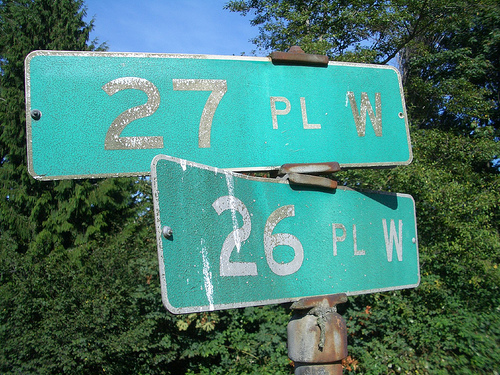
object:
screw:
[162, 226, 174, 242]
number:
[265, 204, 305, 277]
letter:
[300, 97, 324, 130]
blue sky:
[77, 2, 408, 71]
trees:
[1, 223, 162, 374]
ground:
[373, 185, 394, 211]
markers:
[15, 43, 420, 313]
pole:
[288, 293, 345, 374]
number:
[174, 77, 242, 150]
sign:
[21, 47, 414, 182]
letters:
[331, 218, 403, 263]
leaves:
[414, 15, 497, 58]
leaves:
[447, 241, 495, 284]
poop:
[173, 250, 261, 305]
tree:
[4, 1, 146, 236]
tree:
[153, 4, 491, 373]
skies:
[1, 1, 498, 169]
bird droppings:
[199, 236, 216, 311]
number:
[102, 76, 166, 149]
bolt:
[162, 225, 173, 237]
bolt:
[412, 238, 416, 243]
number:
[212, 192, 258, 278]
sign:
[147, 154, 423, 315]